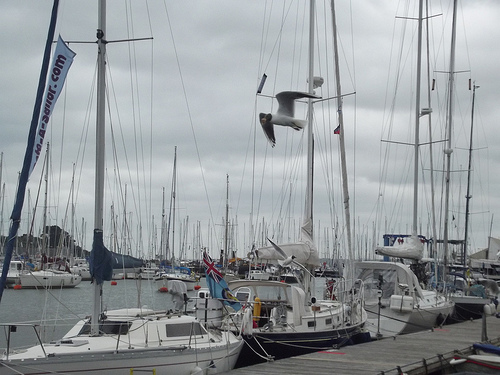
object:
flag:
[202, 246, 242, 312]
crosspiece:
[53, 41, 99, 44]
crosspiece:
[395, 15, 417, 21]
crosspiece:
[379, 139, 416, 148]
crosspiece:
[417, 137, 449, 145]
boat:
[23, 142, 83, 288]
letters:
[53, 53, 67, 68]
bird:
[256, 88, 321, 148]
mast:
[90, 0, 106, 338]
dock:
[215, 315, 500, 374]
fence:
[378, 338, 500, 374]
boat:
[193, 0, 366, 351]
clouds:
[0, 0, 500, 261]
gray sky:
[0, 0, 500, 260]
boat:
[1, 2, 243, 373]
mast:
[299, 0, 315, 291]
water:
[0, 277, 208, 361]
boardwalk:
[218, 314, 499, 374]